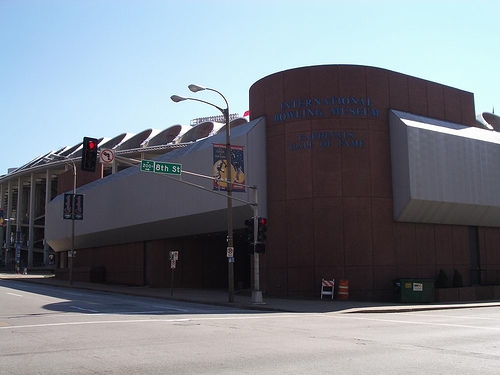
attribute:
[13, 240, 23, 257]
sign — blue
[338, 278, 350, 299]
barrel — orange, white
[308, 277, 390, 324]
barrier — white, striped, orange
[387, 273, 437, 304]
bin — green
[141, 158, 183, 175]
street sign — green, white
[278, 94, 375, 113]
words — blue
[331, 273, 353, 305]
safety cone — large, orange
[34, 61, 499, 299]
building — gray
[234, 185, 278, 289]
grey pole — gray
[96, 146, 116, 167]
street sign — white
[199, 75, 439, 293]
building — large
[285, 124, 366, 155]
words — blue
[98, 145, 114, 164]
arrow — black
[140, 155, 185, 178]
street sign — green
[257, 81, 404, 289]
building — brown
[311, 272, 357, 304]
barricade — a safety barricade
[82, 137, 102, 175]
traffic light — black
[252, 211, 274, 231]
light — red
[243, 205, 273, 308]
pole — metal